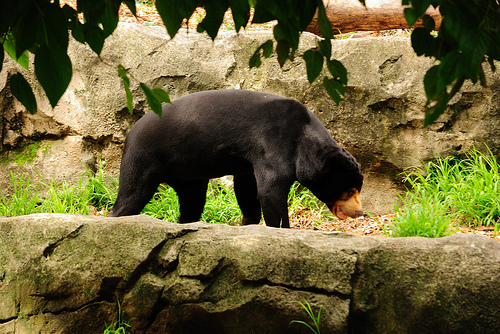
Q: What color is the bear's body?
A: Black.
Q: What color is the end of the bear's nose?
A: Black.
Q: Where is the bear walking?
A: To the right.